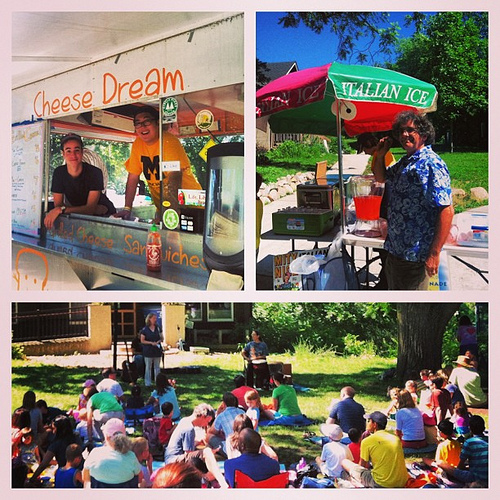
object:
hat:
[60, 131, 81, 146]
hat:
[81, 378, 96, 388]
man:
[131, 327, 146, 379]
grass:
[256, 142, 488, 191]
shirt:
[123, 129, 205, 213]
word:
[140, 154, 167, 181]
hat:
[100, 417, 127, 439]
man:
[82, 416, 145, 489]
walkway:
[255, 232, 489, 290]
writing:
[32, 66, 186, 118]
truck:
[10, 10, 246, 294]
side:
[12, 12, 243, 289]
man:
[222, 426, 282, 489]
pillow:
[405, 472, 438, 488]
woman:
[262, 371, 305, 424]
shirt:
[271, 384, 302, 418]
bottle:
[144, 221, 164, 273]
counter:
[52, 216, 211, 290]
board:
[9, 119, 50, 235]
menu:
[10, 119, 47, 237]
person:
[145, 371, 182, 421]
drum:
[251, 358, 268, 375]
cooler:
[274, 209, 331, 214]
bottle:
[277, 208, 281, 213]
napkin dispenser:
[200, 141, 246, 292]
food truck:
[7, 8, 246, 291]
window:
[47, 98, 160, 226]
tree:
[467, 14, 488, 141]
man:
[339, 409, 410, 487]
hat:
[362, 410, 389, 428]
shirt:
[359, 429, 408, 488]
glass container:
[351, 178, 386, 239]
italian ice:
[350, 181, 385, 238]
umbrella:
[255, 59, 439, 139]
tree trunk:
[390, 299, 442, 384]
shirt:
[381, 144, 455, 265]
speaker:
[240, 330, 271, 392]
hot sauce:
[145, 232, 163, 274]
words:
[11, 128, 41, 234]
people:
[150, 458, 202, 488]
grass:
[9, 352, 487, 488]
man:
[379, 109, 455, 291]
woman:
[241, 330, 271, 391]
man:
[43, 131, 117, 231]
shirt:
[50, 161, 117, 218]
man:
[111, 104, 205, 226]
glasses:
[133, 119, 157, 130]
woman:
[140, 311, 164, 390]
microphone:
[157, 327, 162, 338]